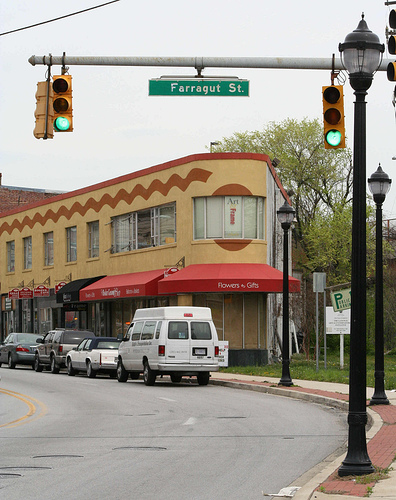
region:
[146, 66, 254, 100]
Hanging overhead street sign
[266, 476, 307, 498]
Piece of paper laying by curb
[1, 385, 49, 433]
Yellow lines painted on the road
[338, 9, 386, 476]
Black light pole with fixture mounted to top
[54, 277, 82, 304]
Black canopy on building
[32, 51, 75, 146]
Hanging traffic lights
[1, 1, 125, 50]
Hanging overhead power line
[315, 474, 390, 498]
Grass growing between bricks on sidewalk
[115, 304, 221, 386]
White van parked by curb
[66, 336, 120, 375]
White car with blue roof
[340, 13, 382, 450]
a light on a light pole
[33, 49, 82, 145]
a traffic light on a pole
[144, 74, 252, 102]
a green and white sign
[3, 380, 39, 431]
a yellow line in the road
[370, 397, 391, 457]
red bricks on a side wall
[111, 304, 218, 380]
a parked white van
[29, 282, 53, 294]
a red and white sign on a building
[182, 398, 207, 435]
a white line on a road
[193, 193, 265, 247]
a window on a building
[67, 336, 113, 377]
a blue and white car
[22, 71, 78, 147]
Yellow traffic signs with green light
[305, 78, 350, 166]
Yellow traffic signs with green light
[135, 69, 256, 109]
Green street sign with white lettering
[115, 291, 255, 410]
Car parked on pavement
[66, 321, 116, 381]
Car parked on pavement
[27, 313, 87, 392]
Car parked on pavement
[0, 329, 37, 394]
Car parked on pavement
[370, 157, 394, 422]
Large black light post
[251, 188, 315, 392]
Large black light post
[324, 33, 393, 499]
Large black light post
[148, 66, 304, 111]
a green stree sign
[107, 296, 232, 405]
a white van parked at curb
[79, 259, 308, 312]
two red awnings on building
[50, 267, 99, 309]
one black awning on building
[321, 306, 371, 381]
a white sign with black writing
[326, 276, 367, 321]
a green parking sign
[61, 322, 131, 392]
a white car with blue top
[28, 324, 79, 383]
a silver SUV in front of car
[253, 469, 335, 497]
a paper on the ground by curb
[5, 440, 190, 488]
four manhole covers in road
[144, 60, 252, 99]
Street sign hanging from pole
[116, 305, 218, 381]
White van parked near curb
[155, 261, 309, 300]
Red awning on building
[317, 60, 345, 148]
Stoplight hanging from pole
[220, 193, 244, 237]
Sign hanging in window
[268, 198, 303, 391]
Tall black street lamp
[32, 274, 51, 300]
Red sign hanging over door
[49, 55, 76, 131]
Traffic light turned green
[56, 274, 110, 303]
Black awning on building